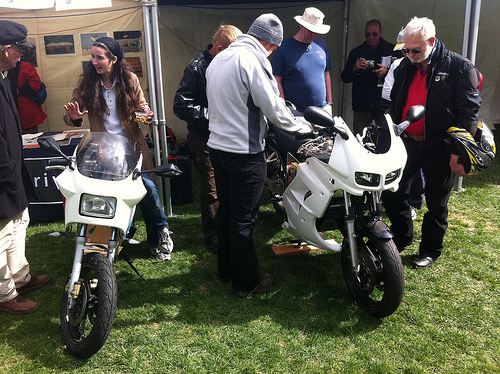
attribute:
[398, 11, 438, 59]
hair — gray 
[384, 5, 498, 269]
man — one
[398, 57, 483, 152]
jacket — one, black 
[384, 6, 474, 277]
man — one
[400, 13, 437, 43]
hair — white, short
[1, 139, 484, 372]
grass — green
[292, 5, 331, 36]
hat — large, white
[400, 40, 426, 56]
sunglasses — dark, black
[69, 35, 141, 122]
hair — long, brown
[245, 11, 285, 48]
cap — gray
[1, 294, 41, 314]
shoe — brown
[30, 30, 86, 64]
picture — hanging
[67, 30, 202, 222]
person — standing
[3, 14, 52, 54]
hat — black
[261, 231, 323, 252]
wood — supporting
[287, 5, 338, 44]
hat — white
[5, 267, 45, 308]
shoes — red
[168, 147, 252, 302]
pants — brown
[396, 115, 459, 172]
belt — orange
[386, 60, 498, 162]
coat — black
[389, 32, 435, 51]
shades — black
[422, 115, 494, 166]
helmet — yellow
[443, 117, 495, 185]
helmet — grey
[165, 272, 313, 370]
grass — green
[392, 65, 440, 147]
shirt — red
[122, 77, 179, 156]
coat — brown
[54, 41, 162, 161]
woman — sitting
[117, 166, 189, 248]
jeans — blue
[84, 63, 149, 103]
scarf — black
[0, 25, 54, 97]
hat — black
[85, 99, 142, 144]
shirt — white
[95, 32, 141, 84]
hair — long, brown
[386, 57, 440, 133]
shirt — red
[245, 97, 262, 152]
stripe — BLUE